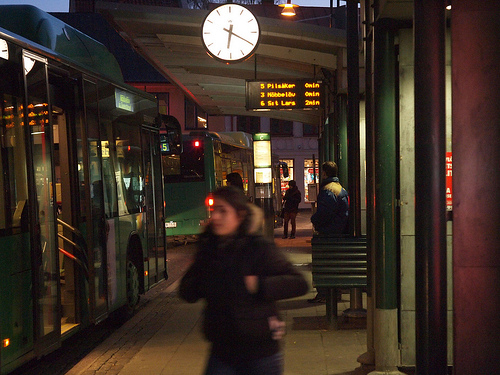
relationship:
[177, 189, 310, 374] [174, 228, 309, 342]
girl wearing jacket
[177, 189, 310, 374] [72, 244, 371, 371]
girl walking on sidewalk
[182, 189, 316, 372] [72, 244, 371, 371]
girl walking down sidewalk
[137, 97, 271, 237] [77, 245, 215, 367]
bus parked at curb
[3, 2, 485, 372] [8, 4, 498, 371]
picture of terminal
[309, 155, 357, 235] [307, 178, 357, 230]
man in jacket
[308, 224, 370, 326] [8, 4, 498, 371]
bench at terminal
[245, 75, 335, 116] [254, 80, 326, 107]
schedule of times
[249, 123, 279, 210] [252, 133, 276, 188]
display of routes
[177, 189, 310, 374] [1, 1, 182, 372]
girl trying to catch bus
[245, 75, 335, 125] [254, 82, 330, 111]
schedule and times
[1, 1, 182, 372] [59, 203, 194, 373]
bus parked next to curb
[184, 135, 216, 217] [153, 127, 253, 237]
lights on back of bus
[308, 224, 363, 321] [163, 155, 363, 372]
bench for passengers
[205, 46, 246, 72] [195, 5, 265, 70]
portion of clock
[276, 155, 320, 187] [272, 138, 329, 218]
lights in stores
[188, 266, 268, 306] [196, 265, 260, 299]
hands in pocket